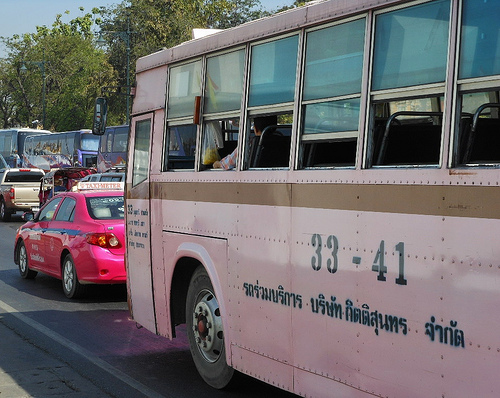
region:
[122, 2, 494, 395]
a bus on a street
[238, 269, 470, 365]
writing on the side of the bus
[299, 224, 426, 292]
the numbers 33-41 on the bus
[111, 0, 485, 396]
the bus is white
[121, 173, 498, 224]
a gold strip on the side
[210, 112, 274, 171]
a passenger in the bus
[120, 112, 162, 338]
a door at the front of the bus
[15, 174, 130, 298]
a taxi in front of the bus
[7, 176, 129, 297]
the taxi is red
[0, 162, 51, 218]
a gold truck on the street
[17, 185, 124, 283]
the car is red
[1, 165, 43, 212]
the truck is white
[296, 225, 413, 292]
the numbers are 33-41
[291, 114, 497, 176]
the seats have no people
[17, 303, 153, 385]
shadow is on the ground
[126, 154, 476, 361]
the bus is pink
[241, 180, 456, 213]
the strip is brown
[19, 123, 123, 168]
the buses are parked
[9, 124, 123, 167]
the buses are three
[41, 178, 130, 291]
the car is a taxi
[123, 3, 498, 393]
large white bus with foreign writing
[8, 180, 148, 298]
red car in front of bus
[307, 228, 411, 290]
33-41 numbers written in green on bus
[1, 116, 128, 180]
three buses on other side of street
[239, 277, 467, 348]
foreign writing on side of bus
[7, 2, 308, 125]
green tall trees on background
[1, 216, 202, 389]
black concrete road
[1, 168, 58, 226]
gold truck in front of red car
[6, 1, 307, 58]
clear blue sunny cloudless sky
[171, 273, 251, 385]
front left hand sided bus tire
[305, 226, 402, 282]
33-41 numbers on side of pink bus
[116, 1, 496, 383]
pink bus on roadway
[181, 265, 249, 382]
front left passenger wheel shown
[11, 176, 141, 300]
red taxi car in Ny is easy.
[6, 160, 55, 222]
brown pick up truck in traffic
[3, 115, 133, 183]
set of three large commercial buses in my lifetime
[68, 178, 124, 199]
white sign indicating taxi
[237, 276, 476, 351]
green foreign Asian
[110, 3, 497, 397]
large pink truck going down asian street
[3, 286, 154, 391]
white lines on concrete street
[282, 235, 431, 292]
numbers on the bus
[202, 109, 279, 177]
passenger on the bus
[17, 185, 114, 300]
pink car in front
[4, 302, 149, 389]
white lines on the road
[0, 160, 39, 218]
truck in the lane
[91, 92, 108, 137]
side mirror on the bus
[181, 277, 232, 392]
black tires on the bus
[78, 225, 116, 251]
red back lights on car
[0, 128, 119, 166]
large buses parked at curb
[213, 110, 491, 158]
windows are opened on the bus